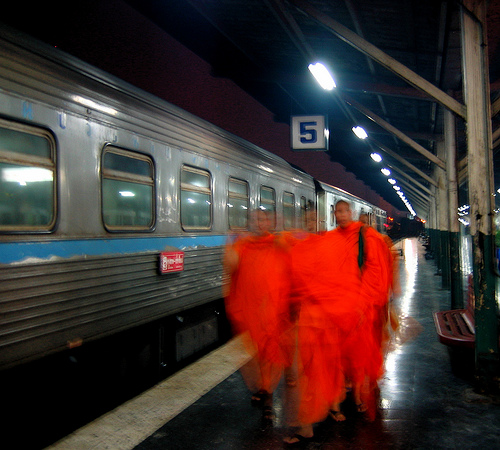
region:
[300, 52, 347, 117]
a outdoor florescent light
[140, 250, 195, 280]
a red sign on train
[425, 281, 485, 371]
a brown bench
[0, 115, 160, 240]
windows on the side of train cart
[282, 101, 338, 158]
blue number 5 on white sign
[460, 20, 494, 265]
brown metal pole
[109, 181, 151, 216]
light reflecting in train window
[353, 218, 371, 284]
a black bag strap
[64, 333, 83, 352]
a orange light on side of train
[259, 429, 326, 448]
a black sandal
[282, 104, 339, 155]
Sign contains a blue number five.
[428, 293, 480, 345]
The bench is red.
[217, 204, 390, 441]
Three men wearing orange gowns.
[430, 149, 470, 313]
The pole is white and green.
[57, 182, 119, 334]
The train is gray with a blue mid border line.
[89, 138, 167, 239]
The windows are a rounded rectangular shape.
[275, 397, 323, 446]
The man is wearing black flip flops.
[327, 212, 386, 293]
Man has a black strapped sack or book bag.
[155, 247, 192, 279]
The sign is red and white.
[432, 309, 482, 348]
The bench has two long slits and two short slits in seat.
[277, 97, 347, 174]
the number five next to train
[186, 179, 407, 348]
group of people in orange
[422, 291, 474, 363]
bench next to men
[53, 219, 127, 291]
blue strip on train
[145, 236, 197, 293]
red sign on the train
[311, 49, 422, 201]
lights on top of the structure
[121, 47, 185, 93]
dark sky above train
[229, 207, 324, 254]
blurry heads of people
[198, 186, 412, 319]
multiple men walking together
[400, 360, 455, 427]
dark ground below men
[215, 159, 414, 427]
the dress is orange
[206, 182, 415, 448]
the monks are walking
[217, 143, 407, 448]
monks at the platform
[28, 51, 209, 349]
the train is silver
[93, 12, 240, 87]
the sky is black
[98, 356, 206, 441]
the line is white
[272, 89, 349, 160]
the number is 5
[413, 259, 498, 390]
the bench is red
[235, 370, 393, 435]
the monks are wearing sandals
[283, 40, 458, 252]
the lights are white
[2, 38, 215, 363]
Part of a passenger trains car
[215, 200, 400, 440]
People dressed in orange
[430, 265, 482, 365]
Bench at a train station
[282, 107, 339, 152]
Marker at a train station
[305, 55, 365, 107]
Light at a train station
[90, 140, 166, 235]
Window on a trains passenger car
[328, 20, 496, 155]
Wooden supports for roof at train station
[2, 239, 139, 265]
Blue stripe on the side of a passenger train car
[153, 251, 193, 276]
Sign on the side of a train car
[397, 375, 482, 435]
Platform at train station